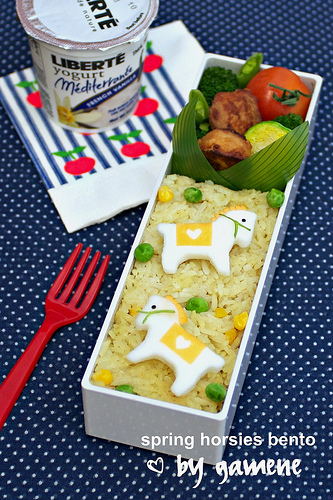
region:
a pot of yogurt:
[15, 2, 164, 139]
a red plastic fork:
[3, 241, 113, 426]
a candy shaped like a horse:
[158, 204, 259, 277]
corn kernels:
[218, 308, 251, 342]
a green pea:
[205, 380, 227, 400]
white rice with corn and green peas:
[179, 276, 258, 343]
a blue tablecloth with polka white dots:
[292, 220, 331, 323]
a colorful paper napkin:
[7, 78, 138, 224]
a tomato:
[251, 66, 308, 123]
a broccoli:
[203, 61, 255, 94]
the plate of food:
[64, 45, 332, 469]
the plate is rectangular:
[58, 36, 322, 498]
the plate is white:
[64, 39, 317, 485]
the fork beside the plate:
[0, 232, 111, 462]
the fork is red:
[2, 234, 127, 432]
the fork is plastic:
[8, 214, 134, 448]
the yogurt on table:
[10, 0, 172, 155]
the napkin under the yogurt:
[4, 5, 248, 215]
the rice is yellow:
[157, 188, 241, 345]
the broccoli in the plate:
[198, 61, 241, 104]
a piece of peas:
[182, 281, 216, 317]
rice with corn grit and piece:
[161, 186, 243, 214]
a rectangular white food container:
[78, 17, 322, 466]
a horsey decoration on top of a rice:
[154, 201, 257, 281]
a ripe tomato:
[244, 62, 315, 121]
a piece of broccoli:
[203, 63, 235, 88]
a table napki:
[1, 138, 109, 233]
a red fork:
[21, 235, 110, 321]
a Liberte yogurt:
[10, 0, 165, 141]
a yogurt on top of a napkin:
[13, 9, 153, 158]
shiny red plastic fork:
[2, 242, 112, 432]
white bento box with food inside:
[75, 48, 330, 467]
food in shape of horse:
[97, 289, 231, 408]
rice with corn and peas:
[91, 354, 138, 397]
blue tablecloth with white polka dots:
[261, 356, 328, 428]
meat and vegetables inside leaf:
[167, 90, 308, 195]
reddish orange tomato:
[243, 65, 310, 122]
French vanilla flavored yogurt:
[12, 1, 161, 137]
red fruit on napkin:
[49, 141, 99, 180]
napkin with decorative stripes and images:
[3, 16, 217, 233]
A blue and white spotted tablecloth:
[0, 430, 89, 498]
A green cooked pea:
[204, 380, 228, 401]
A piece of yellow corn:
[91, 366, 114, 384]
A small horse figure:
[128, 295, 224, 392]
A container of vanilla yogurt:
[14, 0, 159, 126]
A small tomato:
[249, 65, 313, 119]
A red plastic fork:
[0, 247, 109, 394]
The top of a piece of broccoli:
[197, 64, 245, 95]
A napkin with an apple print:
[13, 82, 159, 215]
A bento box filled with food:
[82, 49, 329, 434]